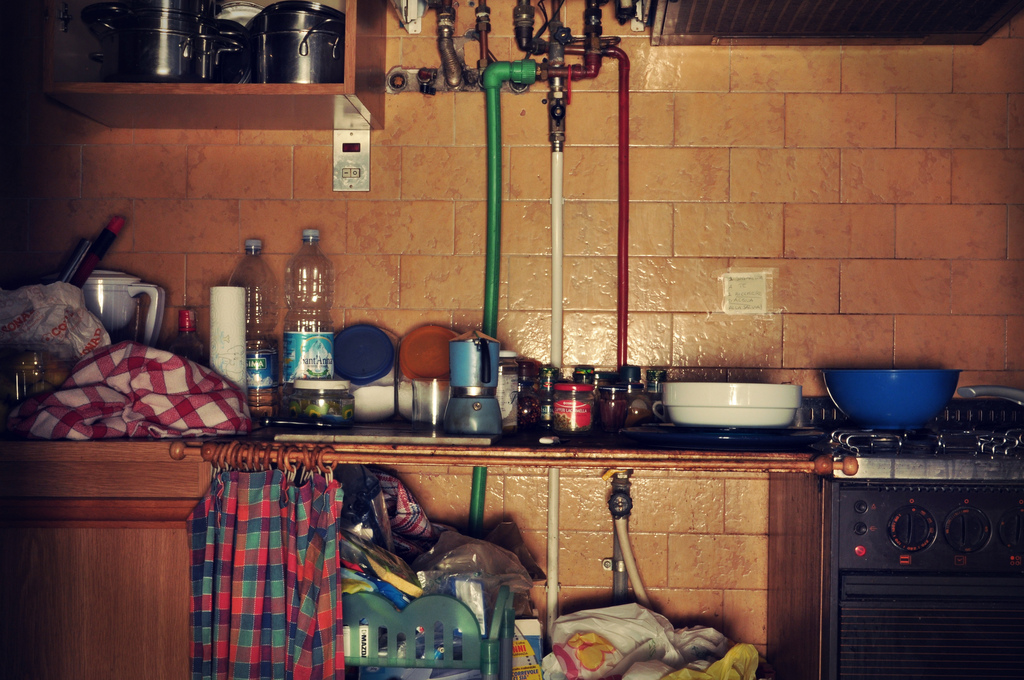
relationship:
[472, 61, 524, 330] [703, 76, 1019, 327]
green pipe on wall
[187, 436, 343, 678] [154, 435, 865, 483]
curtain on a pole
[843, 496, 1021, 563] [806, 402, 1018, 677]
knobs on cooking range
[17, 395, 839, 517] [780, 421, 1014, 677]
countertop beside a stove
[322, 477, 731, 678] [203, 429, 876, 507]
stuff under counter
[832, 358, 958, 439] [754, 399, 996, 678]
serving bowl on top of stove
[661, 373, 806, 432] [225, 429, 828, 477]
bowl on counter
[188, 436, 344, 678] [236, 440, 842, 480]
curtain on counter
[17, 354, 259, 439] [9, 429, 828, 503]
cloth wadded up on counter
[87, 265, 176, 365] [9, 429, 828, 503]
blender container on counter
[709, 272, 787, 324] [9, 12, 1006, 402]
paper taped to wall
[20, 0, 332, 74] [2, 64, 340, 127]
pans on shelf